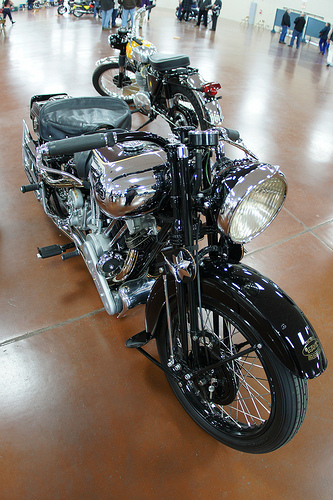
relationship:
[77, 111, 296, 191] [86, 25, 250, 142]
handlebars on motorcycle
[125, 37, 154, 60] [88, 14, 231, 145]
yellow detailing on motorcycle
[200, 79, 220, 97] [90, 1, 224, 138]
light on motorcycle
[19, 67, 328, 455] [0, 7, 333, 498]
bike on floor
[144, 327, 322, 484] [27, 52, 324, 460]
tire on bike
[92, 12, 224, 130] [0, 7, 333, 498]
bike on floor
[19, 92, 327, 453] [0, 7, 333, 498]
bike on floor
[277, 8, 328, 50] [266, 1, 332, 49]
people standing near boards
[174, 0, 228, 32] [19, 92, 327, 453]
people standing near bike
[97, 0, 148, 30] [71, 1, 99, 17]
people standing near bike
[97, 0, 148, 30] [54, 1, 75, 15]
people standing near bike